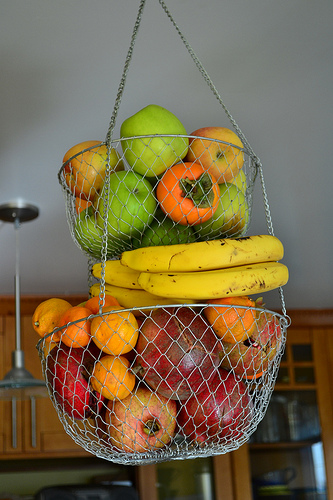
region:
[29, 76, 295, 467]
fruit hanging from the wall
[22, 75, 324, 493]
fruit hanging from a wire basket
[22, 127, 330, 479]
two wire baskets filled with fruit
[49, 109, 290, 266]
wire basket filled with fruit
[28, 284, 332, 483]
wire basket filled with fruit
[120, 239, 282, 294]
yellow banana in pile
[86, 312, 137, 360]
orange in the basket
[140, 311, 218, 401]
mango in the basket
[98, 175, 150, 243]
pear in the basket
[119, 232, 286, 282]
banana in the basket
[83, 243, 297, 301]
the bananas are yellow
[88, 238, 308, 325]
the bananas are yellow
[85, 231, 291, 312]
the bananas are yellow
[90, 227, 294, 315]
the bananas are yellow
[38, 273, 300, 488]
fruits in the basket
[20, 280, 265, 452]
fruits in the basket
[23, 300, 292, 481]
fruits in the basket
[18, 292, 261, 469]
fruits in the basket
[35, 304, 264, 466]
fruits in the basket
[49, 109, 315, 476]
A fruit basket hanging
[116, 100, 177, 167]
A fresh green apple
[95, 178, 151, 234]
A fresh green apple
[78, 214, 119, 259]
A fresh green apple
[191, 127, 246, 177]
A fresh pink apple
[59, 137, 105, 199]
A fresh pink apple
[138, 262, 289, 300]
A fresh yellow banana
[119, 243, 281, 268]
A fresh yellow banana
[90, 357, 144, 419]
A small fresh orange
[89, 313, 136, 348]
A small fresh orange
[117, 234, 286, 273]
a banana in a metal basket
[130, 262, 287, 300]
a banana in a metal basket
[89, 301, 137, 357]
an orange in a metal basket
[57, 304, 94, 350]
an orange in a metal basket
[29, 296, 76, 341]
an orange in a metal basket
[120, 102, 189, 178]
an apple in a metal basket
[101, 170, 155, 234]
an apple in a metal basket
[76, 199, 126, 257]
an apple in a metal basket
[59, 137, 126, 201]
an apple in a metal basket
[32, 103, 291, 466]
a collection of fruits in a metal basket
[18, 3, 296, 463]
this is a hanging basket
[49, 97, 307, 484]
hanging basket full of fruit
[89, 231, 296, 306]
bunch of yellow bananas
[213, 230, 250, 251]
brown spots on bananas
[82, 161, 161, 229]
green apple in basket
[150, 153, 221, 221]
a orange in the basket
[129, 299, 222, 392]
red pomegranate in basket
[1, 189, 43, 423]
a hanging kitchen light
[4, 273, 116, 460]
brown kitchen cabinets in background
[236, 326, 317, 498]
glass door cabinets in background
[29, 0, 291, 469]
fruit inside of a hanging metal basket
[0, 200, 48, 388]
silver metal light fixture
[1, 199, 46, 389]
light hanging from a kitchen ceiling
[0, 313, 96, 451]
brown cabinet doors with silver handles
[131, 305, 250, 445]
two red pomegranates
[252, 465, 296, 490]
blue pot on top of green plate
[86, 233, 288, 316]
bunch of yellow bananas